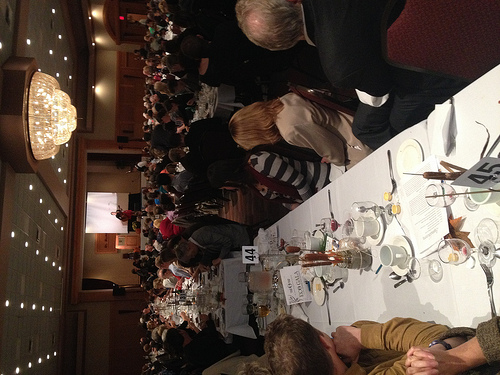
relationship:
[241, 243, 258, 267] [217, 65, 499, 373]
44 on a table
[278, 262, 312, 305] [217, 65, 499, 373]
name card on a table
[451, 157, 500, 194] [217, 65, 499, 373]
45 on a table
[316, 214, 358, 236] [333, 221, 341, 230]
wineglass has red wine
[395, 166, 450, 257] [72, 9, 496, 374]
agenda of conference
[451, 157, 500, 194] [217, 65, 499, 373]
45 on table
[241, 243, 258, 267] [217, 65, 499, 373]
44 on table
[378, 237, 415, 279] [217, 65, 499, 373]
cup and saucer on table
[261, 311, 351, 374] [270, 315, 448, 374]
head of a man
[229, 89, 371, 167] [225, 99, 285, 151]
woman has blond hair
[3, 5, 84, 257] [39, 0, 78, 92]
ceiling has tiny lights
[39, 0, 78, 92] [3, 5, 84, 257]
tiny lights on ceiling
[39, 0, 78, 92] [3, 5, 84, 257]
tiny lights in ceiling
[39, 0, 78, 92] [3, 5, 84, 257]
tiny lights are lit in ceiling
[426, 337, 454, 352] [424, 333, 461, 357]
watch on a wrist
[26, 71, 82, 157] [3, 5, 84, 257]
chandelier on ceiling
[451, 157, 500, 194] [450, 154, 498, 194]
45 on a sign